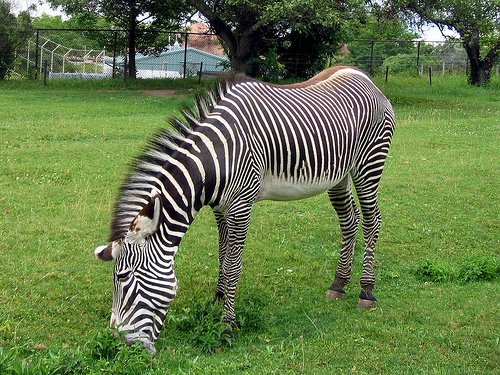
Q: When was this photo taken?
A: During the day.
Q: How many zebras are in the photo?
A: One.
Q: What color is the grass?
A: Green.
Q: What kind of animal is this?
A: A zebra.